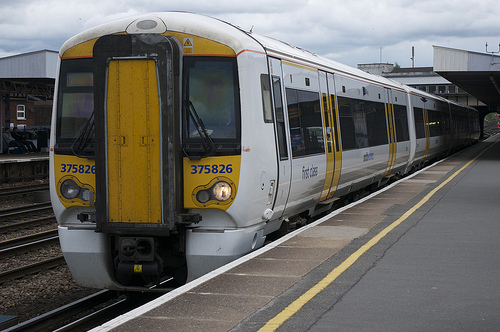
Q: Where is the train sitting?
A: Tracks.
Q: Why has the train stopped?
A: Station.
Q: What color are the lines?
A: White and yellow.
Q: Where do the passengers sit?
A: Cars.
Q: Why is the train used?
A: Transportation.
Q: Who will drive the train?
A: Engineer.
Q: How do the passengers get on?
A: Doors.